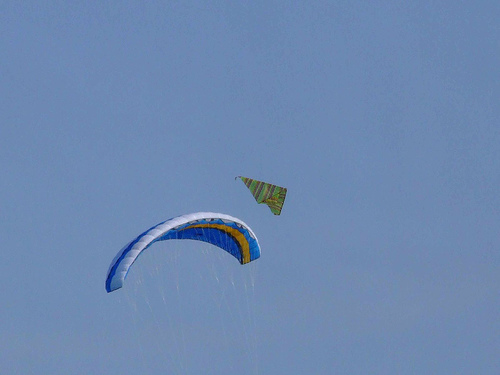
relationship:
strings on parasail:
[114, 233, 270, 373] [100, 210, 265, 292]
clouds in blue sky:
[417, 112, 477, 281] [0, 0, 499, 374]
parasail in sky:
[98, 208, 266, 373] [283, 24, 495, 329]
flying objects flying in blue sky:
[231, 175, 286, 217] [0, 0, 499, 374]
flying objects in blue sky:
[231, 170, 290, 218] [0, 0, 499, 374]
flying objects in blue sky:
[231, 175, 286, 217] [0, 0, 499, 374]